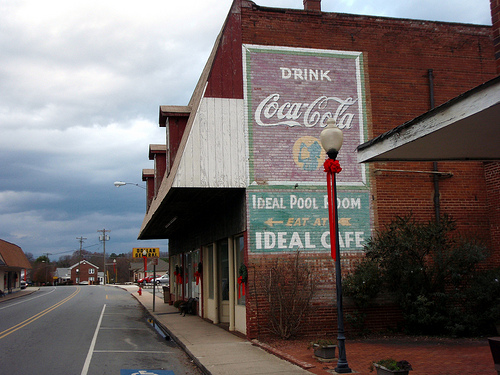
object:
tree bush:
[337, 212, 500, 343]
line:
[69, 300, 111, 375]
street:
[6, 286, 199, 374]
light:
[302, 114, 359, 372]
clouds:
[1, 0, 228, 131]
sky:
[2, 2, 493, 262]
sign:
[132, 244, 161, 259]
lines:
[0, 286, 55, 309]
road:
[1, 282, 211, 373]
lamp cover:
[317, 119, 343, 161]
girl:
[47, 284, 117, 364]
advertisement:
[241, 45, 371, 259]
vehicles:
[136, 273, 161, 285]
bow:
[271, 101, 369, 339]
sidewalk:
[119, 277, 300, 374]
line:
[16, 296, 67, 333]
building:
[129, 0, 499, 342]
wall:
[238, 1, 500, 341]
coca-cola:
[252, 89, 356, 131]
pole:
[323, 157, 352, 373]